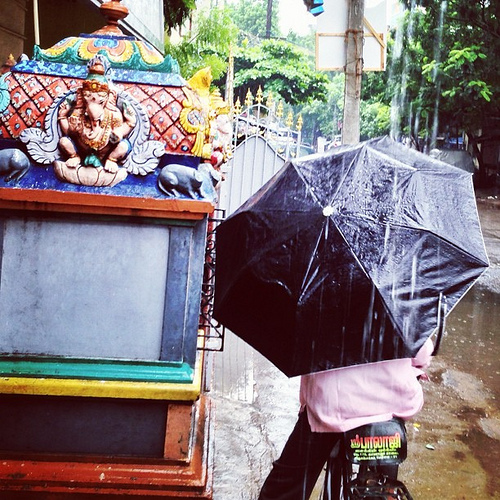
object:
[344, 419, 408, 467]
back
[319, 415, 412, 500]
bicycle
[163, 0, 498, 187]
trees